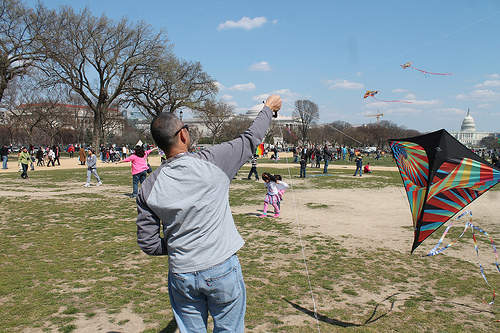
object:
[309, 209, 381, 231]
tan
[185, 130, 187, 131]
specks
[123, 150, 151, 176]
t-shirt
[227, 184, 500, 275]
sand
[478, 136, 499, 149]
tree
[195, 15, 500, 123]
clouds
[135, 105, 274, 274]
shirt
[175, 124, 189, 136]
sunglasses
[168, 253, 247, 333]
jeans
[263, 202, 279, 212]
tights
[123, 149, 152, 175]
sweater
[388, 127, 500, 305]
kite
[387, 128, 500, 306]
design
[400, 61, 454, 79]
kite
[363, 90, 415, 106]
kite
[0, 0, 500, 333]
park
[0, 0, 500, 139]
sky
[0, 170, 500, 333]
spots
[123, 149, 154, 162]
arms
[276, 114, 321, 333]
rope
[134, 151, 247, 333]
back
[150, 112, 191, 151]
head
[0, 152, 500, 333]
field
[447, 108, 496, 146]
building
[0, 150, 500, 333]
ground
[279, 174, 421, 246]
dirt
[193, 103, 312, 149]
building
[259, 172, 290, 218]
child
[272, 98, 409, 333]
kite string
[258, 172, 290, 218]
kids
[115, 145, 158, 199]
lady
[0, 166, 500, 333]
grass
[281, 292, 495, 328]
shadow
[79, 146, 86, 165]
people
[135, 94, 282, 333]
man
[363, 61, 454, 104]
two kites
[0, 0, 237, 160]
tall trees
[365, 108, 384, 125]
cane